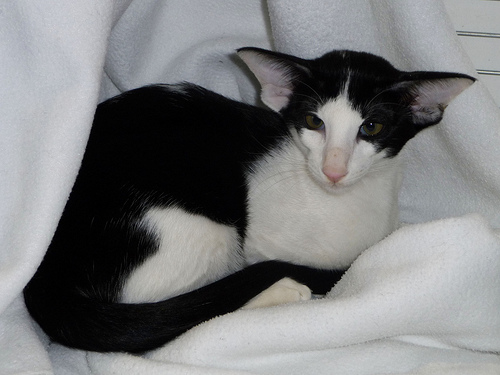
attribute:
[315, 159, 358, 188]
nose — pink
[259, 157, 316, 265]
fur — white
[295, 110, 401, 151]
eyes — light, brownish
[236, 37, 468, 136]
ears — black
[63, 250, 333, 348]
tail — black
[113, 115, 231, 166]
fur — black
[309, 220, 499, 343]
towel — white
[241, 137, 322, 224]
whiskers — white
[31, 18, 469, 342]
cat — black, white, focusing